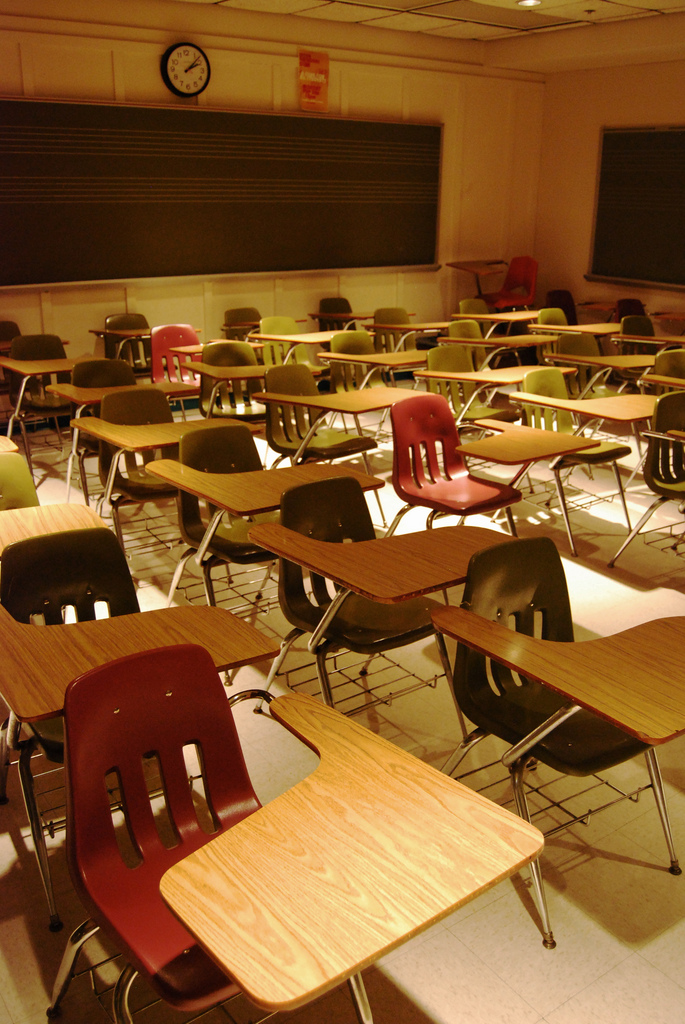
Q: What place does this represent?
A: It represents the classroom.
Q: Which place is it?
A: It is a classroom.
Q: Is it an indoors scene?
A: Yes, it is indoors.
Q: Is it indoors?
A: Yes, it is indoors.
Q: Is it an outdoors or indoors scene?
A: It is indoors.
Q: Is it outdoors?
A: No, it is indoors.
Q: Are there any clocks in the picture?
A: Yes, there is a clock.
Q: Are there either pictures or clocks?
A: Yes, there is a clock.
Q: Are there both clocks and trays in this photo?
A: No, there is a clock but no trays.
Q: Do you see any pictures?
A: No, there are no pictures.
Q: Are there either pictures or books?
A: No, there are no pictures or books.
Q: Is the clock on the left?
A: Yes, the clock is on the left of the image.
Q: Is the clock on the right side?
A: No, the clock is on the left of the image.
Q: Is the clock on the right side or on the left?
A: The clock is on the left of the image.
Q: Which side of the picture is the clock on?
A: The clock is on the left of the image.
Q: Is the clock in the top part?
A: Yes, the clock is in the top of the image.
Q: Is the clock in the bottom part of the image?
A: No, the clock is in the top of the image.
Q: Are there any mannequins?
A: No, there are no mannequins.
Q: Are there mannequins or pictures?
A: No, there are no mannequins or pictures.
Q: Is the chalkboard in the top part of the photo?
A: Yes, the chalkboard is in the top of the image.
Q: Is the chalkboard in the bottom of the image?
A: No, the chalkboard is in the top of the image.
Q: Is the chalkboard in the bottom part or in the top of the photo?
A: The chalkboard is in the top of the image.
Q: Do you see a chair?
A: Yes, there is a chair.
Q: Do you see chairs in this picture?
A: Yes, there is a chair.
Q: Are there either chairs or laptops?
A: Yes, there is a chair.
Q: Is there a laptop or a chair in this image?
A: Yes, there is a chair.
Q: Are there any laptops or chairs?
A: Yes, there is a chair.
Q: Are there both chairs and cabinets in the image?
A: No, there is a chair but no cabinets.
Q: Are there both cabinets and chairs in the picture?
A: No, there is a chair but no cabinets.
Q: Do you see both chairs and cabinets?
A: No, there is a chair but no cabinets.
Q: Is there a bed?
A: No, there are no beds.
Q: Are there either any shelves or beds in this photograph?
A: No, there are no beds or shelves.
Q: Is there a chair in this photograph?
A: Yes, there is a chair.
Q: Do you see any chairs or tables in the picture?
A: Yes, there is a chair.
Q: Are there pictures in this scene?
A: No, there are no pictures.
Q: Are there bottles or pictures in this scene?
A: No, there are no pictures or bottles.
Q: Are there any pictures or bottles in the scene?
A: No, there are no pictures or bottles.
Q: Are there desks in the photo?
A: Yes, there is a desk.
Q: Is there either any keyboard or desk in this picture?
A: Yes, there is a desk.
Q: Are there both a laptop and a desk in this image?
A: No, there is a desk but no laptops.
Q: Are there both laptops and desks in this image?
A: No, there is a desk but no laptops.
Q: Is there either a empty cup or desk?
A: Yes, there is an empty desk.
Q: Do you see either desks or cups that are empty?
A: Yes, the desk is empty.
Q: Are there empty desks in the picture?
A: Yes, there is an empty desk.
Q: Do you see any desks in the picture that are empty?
A: Yes, there is a desk that is empty.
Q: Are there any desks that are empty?
A: Yes, there is a desk that is empty.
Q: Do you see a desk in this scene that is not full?
A: Yes, there is a empty desk.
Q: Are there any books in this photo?
A: No, there are no books.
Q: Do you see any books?
A: No, there are no books.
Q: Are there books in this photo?
A: No, there are no books.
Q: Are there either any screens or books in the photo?
A: No, there are no books or screens.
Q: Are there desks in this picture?
A: Yes, there is a desk.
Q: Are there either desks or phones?
A: Yes, there is a desk.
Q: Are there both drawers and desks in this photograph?
A: No, there is a desk but no drawers.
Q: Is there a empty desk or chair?
A: Yes, there is an empty desk.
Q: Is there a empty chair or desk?
A: Yes, there is an empty desk.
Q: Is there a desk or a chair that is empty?
A: Yes, the desk is empty.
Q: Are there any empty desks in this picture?
A: Yes, there is an empty desk.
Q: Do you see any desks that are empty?
A: Yes, there is a desk that is empty.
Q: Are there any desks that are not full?
A: Yes, there is a empty desk.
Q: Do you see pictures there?
A: No, there are no pictures.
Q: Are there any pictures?
A: No, there are no pictures.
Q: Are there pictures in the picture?
A: No, there are no pictures.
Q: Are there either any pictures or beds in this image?
A: No, there are no pictures or beds.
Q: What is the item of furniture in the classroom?
A: The piece of furniture is a desk.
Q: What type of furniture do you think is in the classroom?
A: The piece of furniture is a desk.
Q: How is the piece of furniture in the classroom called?
A: The piece of furniture is a desk.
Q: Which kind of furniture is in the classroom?
A: The piece of furniture is a desk.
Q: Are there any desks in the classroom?
A: Yes, there is a desk in the classroom.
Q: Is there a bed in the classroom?
A: No, there is a desk in the classroom.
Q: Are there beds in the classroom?
A: No, there is a desk in the classroom.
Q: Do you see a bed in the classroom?
A: No, there is a desk in the classroom.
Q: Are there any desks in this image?
A: Yes, there is a desk.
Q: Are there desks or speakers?
A: Yes, there is a desk.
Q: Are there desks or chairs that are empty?
A: Yes, the desk is empty.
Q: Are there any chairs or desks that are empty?
A: Yes, the desk is empty.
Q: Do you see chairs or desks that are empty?
A: Yes, the desk is empty.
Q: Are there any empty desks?
A: Yes, there is an empty desk.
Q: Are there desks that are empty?
A: Yes, there is a desk that is empty.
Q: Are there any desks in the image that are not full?
A: Yes, there is a empty desk.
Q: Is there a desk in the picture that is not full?
A: Yes, there is a empty desk.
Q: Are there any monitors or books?
A: No, there are no books or monitors.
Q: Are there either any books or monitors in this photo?
A: No, there are no books or monitors.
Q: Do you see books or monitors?
A: No, there are no books or monitors.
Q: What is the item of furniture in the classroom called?
A: The piece of furniture is a desk.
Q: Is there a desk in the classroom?
A: Yes, there is a desk in the classroom.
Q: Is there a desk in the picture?
A: Yes, there is a desk.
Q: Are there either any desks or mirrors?
A: Yes, there is a desk.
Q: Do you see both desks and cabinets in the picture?
A: No, there is a desk but no cabinets.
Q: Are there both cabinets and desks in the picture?
A: No, there is a desk but no cabinets.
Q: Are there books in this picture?
A: No, there are no books.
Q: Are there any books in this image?
A: No, there are no books.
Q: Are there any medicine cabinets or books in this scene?
A: No, there are no books or medicine cabinets.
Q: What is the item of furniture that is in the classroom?
A: The piece of furniture is a desk.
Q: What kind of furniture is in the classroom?
A: The piece of furniture is a desk.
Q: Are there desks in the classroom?
A: Yes, there is a desk in the classroom.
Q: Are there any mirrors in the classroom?
A: No, there is a desk in the classroom.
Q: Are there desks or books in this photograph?
A: Yes, there is a desk.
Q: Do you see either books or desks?
A: Yes, there is a desk.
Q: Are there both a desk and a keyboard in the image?
A: No, there is a desk but no keyboards.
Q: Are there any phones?
A: No, there are no phones.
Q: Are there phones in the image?
A: No, there are no phones.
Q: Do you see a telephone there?
A: No, there are no phones.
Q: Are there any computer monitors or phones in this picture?
A: No, there are no phones or computer monitors.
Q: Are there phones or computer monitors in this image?
A: No, there are no phones or computer monitors.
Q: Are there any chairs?
A: Yes, there is a chair.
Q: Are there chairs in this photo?
A: Yes, there is a chair.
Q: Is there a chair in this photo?
A: Yes, there is a chair.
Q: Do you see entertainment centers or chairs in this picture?
A: Yes, there is a chair.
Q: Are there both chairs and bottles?
A: No, there is a chair but no bottles.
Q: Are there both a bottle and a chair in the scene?
A: No, there is a chair but no bottles.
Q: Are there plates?
A: No, there are no plates.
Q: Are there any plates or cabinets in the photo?
A: No, there are no plates or cabinets.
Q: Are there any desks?
A: Yes, there is a desk.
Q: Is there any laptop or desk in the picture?
A: Yes, there is a desk.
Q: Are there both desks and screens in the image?
A: No, there is a desk but no screens.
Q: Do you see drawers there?
A: No, there are no drawers.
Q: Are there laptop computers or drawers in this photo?
A: No, there are no drawers or laptop computers.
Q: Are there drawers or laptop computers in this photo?
A: No, there are no drawers or laptop computers.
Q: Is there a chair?
A: Yes, there is a chair.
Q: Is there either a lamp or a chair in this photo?
A: Yes, there is a chair.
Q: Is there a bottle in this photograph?
A: No, there are no bottles.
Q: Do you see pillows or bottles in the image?
A: No, there are no bottles or pillows.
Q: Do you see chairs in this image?
A: Yes, there is a chair.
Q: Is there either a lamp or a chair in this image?
A: Yes, there is a chair.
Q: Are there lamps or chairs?
A: Yes, there is a chair.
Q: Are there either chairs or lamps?
A: Yes, there is a chair.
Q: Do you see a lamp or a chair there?
A: Yes, there is a chair.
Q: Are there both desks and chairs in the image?
A: Yes, there are both a chair and a desk.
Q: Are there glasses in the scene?
A: No, there are no glasses.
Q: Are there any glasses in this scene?
A: No, there are no glasses.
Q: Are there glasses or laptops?
A: No, there are no glasses or laptops.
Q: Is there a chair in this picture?
A: Yes, there is a chair.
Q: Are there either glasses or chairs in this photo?
A: Yes, there is a chair.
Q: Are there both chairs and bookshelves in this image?
A: No, there is a chair but no bookshelves.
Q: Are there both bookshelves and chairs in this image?
A: No, there is a chair but no bookshelves.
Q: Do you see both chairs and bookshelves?
A: No, there is a chair but no bookshelves.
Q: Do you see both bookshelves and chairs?
A: No, there is a chair but no bookshelves.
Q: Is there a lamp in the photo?
A: No, there are no lamps.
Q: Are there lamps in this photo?
A: No, there are no lamps.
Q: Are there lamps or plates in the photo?
A: No, there are no lamps or plates.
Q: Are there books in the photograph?
A: No, there are no books.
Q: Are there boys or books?
A: No, there are no books or boys.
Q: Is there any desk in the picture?
A: Yes, there is a desk.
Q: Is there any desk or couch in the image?
A: Yes, there is a desk.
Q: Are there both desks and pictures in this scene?
A: No, there is a desk but no pictures.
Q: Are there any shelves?
A: No, there are no shelves.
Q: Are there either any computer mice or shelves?
A: No, there are no shelves or computer mice.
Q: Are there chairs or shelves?
A: Yes, there is a chair.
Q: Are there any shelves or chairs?
A: Yes, there is a chair.